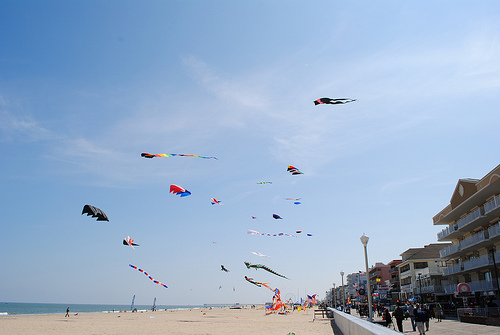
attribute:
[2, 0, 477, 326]
picture — day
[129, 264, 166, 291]
kite — snake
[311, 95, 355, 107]
kite — flying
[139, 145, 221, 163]
kite — flying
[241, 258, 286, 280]
kite — flying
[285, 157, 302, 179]
kite — flying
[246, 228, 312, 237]
kite — flying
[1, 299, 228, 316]
ocean — pictured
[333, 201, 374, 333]
pole — long, tall, light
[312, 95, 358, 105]
kite — multi colored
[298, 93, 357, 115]
kite — rainbow.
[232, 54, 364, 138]
kite — flying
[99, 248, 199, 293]
kite — flying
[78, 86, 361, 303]
kites — many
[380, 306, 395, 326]
person — group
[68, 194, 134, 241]
kite — black.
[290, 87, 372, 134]
kite — many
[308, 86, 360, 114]
kite — flying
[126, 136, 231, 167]
kite — flying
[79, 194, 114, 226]
kite — flying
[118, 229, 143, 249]
kite — flying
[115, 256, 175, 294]
kite — flying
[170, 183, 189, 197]
kite — blue , Yellow, red 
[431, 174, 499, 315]
balconies — building 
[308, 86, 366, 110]
kite — flying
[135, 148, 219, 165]
kite — flying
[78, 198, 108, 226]
kite — flying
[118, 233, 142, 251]
kite — flying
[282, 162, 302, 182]
kite — flying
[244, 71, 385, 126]
kite — blue,, red, yellow 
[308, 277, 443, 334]
people — Several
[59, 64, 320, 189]
clouds — white